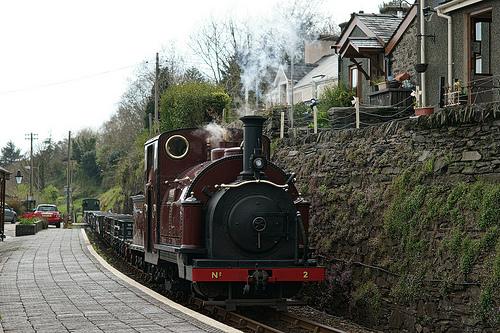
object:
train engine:
[129, 115, 329, 312]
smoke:
[190, 0, 318, 148]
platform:
[0, 226, 246, 333]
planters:
[15, 222, 38, 236]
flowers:
[20, 211, 38, 219]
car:
[33, 204, 62, 228]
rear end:
[34, 211, 61, 223]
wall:
[274, 101, 499, 332]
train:
[82, 116, 328, 313]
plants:
[384, 158, 497, 319]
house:
[417, 0, 500, 107]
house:
[383, 3, 415, 95]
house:
[331, 10, 390, 106]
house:
[292, 53, 340, 106]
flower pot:
[413, 62, 428, 73]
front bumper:
[185, 266, 328, 282]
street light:
[14, 169, 23, 184]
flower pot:
[414, 106, 435, 117]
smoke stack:
[238, 116, 268, 177]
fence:
[279, 74, 500, 138]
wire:
[359, 93, 415, 109]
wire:
[357, 103, 416, 118]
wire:
[359, 105, 420, 119]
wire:
[317, 103, 354, 113]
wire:
[316, 112, 357, 121]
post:
[415, 85, 421, 109]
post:
[354, 97, 359, 128]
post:
[311, 108, 318, 135]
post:
[280, 112, 285, 140]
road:
[0, 221, 251, 332]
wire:
[30, 58, 157, 91]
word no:
[211, 271, 223, 279]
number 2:
[303, 271, 309, 280]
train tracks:
[83, 240, 340, 332]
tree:
[143, 66, 173, 130]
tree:
[81, 148, 105, 187]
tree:
[1, 139, 31, 171]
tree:
[70, 135, 94, 163]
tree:
[178, 66, 201, 86]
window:
[165, 134, 191, 159]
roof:
[357, 13, 406, 43]